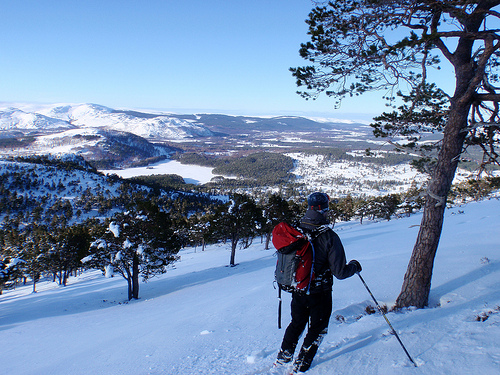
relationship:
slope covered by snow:
[1, 203, 500, 372] [3, 98, 500, 371]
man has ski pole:
[268, 183, 367, 374] [356, 266, 434, 373]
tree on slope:
[298, 0, 499, 319] [1, 203, 500, 372]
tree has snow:
[298, 0, 499, 319] [3, 98, 500, 371]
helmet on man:
[308, 190, 332, 210] [268, 183, 367, 374]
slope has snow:
[1, 203, 500, 372] [3, 98, 500, 371]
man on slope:
[268, 183, 367, 374] [1, 203, 500, 372]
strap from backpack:
[274, 285, 286, 329] [270, 219, 315, 298]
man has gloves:
[268, 183, 367, 374] [351, 254, 362, 274]